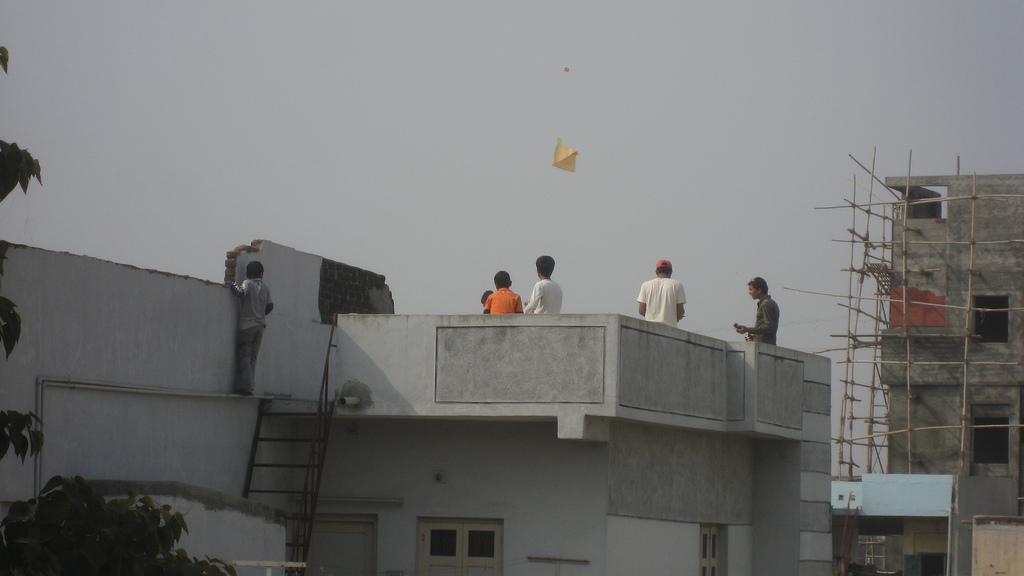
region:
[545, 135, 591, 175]
a light yellow kite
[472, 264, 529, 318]
person wearing an orange shirt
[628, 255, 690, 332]
person wearing a white tee shirt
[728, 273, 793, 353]
person wearing a brown shirt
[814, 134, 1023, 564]
a scaffolding with blue plank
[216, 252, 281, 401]
person in grey pants and white shirt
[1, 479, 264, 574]
spme green leafy plants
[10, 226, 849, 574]
a white building with small windows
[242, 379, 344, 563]
a brown wooden ladder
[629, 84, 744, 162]
the sky is grey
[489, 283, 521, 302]
an orange shirt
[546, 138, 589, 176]
a kite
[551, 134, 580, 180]
the kite in the sky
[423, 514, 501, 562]
a door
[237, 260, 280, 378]
a person standing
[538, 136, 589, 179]
the kite is yellow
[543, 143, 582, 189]
a yellow kite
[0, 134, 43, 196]
a leaf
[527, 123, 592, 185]
yellow kite in air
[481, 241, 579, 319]
men sitting on roof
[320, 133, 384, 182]
white clouds in blue sky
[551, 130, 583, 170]
a yellow kite in the sky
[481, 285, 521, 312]
an orange shirt on a boy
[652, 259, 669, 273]
a red hat on a man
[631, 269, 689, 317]
a white shirt on a man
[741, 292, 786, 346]
a black shirt on a man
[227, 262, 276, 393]
a boy peeking over a ledge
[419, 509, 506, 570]
a set of double doors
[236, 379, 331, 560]
a metal attached ladder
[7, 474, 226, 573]
a green unkempt bush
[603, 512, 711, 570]
a white metal garage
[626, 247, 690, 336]
person standing on the roof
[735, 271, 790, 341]
person standing on the roof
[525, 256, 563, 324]
person standing on the roof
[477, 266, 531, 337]
person standing on the roof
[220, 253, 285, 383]
person standing on the roof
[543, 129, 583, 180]
kite flying in the sky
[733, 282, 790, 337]
man wearing a grey shirt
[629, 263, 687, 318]
man wearing a white shirt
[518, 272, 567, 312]
man wearing a white shirt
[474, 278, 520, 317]
man wearing a orange shirt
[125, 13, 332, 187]
Large body of skies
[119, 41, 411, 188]
Large body of skies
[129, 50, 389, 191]
Large body of skies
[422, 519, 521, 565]
the door on the building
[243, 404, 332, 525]
stairs on the building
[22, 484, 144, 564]
leaves on the tree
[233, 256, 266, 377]
a person standing on the building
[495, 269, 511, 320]
a person in an orange shirt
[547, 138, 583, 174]
a yellow kite in the sky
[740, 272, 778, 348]
a man in a grey shirt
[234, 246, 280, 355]
a man wearing a shirt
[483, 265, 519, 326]
a man wearing a shirt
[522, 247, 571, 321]
a man wearing a shirt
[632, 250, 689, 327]
a man wearing a shirt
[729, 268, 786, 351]
a man wearing a shirt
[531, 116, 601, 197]
a kite flying on the sky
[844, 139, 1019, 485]
a building under construction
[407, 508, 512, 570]
doors of a building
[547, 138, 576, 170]
a kite in the sky